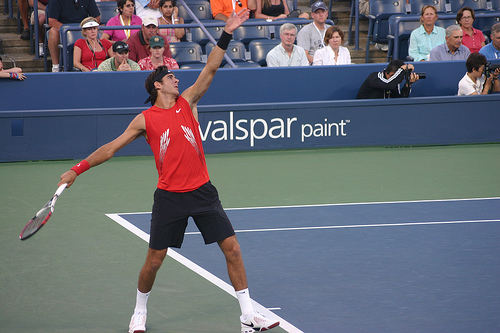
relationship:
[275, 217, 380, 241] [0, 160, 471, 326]
lines on court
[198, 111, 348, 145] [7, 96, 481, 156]
letter on wall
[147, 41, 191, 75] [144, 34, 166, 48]
woman wearing hat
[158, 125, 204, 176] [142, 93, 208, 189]
design on shirt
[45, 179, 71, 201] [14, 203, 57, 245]
handle on racket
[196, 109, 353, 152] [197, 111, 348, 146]
letters showing name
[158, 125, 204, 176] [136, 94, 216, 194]
design printed on shirt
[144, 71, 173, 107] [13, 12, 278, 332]
head band on head of man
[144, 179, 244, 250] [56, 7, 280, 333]
shorts on man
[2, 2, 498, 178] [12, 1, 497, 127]
stands filled with spectators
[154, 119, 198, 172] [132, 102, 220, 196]
design on shirt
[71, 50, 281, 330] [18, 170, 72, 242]
man holding tennis racket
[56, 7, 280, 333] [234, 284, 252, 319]
man wearing socks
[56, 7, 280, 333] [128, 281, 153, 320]
man wearing socks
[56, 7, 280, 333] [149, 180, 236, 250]
man wearing shorts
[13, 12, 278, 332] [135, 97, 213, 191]
man wearing shirt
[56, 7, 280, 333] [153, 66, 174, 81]
man wearing head band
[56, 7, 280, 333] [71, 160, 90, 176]
man wearing armband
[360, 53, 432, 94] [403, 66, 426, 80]
man wearing camera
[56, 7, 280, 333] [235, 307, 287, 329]
man wearing shoe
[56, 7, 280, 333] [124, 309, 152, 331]
man wearing shoe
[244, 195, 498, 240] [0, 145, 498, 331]
line on ground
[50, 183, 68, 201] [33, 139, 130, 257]
handle on a racket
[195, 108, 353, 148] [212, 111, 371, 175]
name on wall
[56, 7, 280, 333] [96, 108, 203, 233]
man playing tennis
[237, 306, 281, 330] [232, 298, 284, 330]
shoe on man's foot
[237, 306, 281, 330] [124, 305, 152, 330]
shoe on man's foot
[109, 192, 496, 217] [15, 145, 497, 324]
line on court